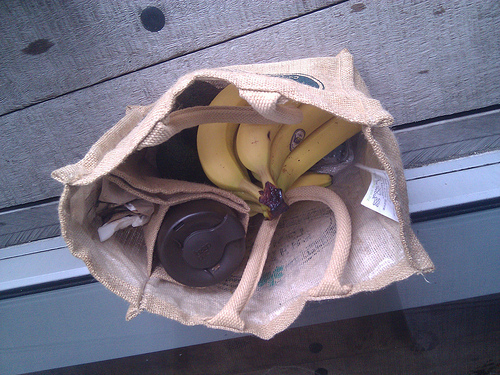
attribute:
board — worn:
[0, 1, 345, 116]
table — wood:
[0, 3, 497, 250]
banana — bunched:
[295, 120, 345, 174]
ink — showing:
[263, 214, 334, 271]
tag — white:
[357, 162, 399, 220]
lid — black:
[156, 202, 250, 284]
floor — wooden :
[0, 2, 499, 374]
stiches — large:
[128, 285, 147, 299]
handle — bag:
[208, 183, 353, 322]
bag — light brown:
[50, 50, 435, 340]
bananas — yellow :
[176, 55, 351, 221]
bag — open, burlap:
[84, 126, 131, 172]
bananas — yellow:
[192, 86, 374, 221]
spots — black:
[132, 2, 175, 42]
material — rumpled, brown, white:
[93, 205, 160, 250]